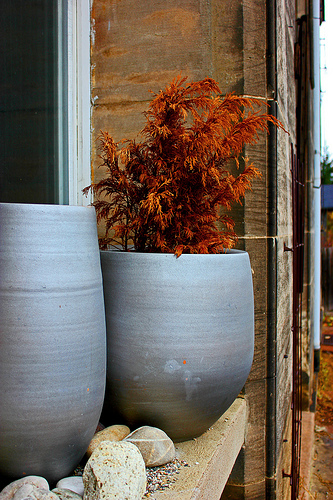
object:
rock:
[82, 440, 147, 500]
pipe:
[312, 0, 320, 372]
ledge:
[0, 393, 248, 500]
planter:
[101, 246, 256, 443]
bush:
[81, 69, 291, 259]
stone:
[122, 425, 175, 468]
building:
[0, 0, 310, 498]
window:
[0, 1, 90, 206]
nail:
[284, 241, 304, 252]